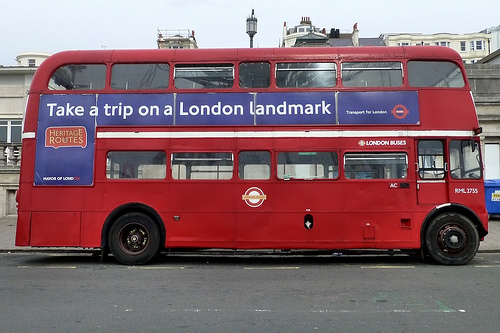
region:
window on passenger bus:
[43, 59, 105, 86]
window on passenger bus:
[168, 59, 239, 88]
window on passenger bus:
[236, 60, 276, 86]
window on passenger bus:
[275, 56, 334, 86]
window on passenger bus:
[338, 55, 402, 95]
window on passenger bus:
[405, 57, 468, 91]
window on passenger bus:
[102, 143, 170, 176]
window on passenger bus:
[168, 141, 235, 178]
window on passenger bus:
[236, 143, 278, 188]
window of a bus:
[399, 50, 466, 92]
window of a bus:
[337, 48, 407, 93]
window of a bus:
[238, 53, 279, 86]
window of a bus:
[170, 56, 235, 93]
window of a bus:
[46, 61, 111, 101]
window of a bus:
[100, 136, 170, 182]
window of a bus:
[176, 145, 231, 185]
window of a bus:
[238, 153, 273, 183]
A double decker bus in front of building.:
[12, 44, 492, 261]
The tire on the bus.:
[107, 219, 161, 271]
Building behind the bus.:
[11, 43, 73, 118]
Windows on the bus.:
[145, 53, 355, 93]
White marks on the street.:
[154, 294, 471, 313]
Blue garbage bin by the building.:
[476, 169, 499, 216]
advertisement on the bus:
[56, 90, 412, 131]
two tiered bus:
[45, 72, 480, 254]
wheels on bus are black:
[97, 212, 176, 276]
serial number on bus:
[438, 183, 485, 205]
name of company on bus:
[361, 136, 406, 146]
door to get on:
[412, 141, 452, 230]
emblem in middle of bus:
[236, 179, 268, 233]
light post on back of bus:
[243, 0, 260, 49]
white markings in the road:
[108, 297, 445, 321]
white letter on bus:
[46, 100, 56, 115]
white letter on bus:
[54, 103, 64, 118]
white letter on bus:
[64, 100, 74, 115]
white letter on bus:
[73, 104, 83, 116]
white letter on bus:
[89, 107, 100, 115]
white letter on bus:
[101, 100, 112, 117]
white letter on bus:
[109, 101, 117, 114]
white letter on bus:
[116, 100, 123, 120]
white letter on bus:
[121, 105, 132, 122]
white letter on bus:
[139, 105, 149, 115]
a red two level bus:
[9, 27, 491, 274]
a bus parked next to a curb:
[16, 37, 489, 275]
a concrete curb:
[482, 241, 498, 256]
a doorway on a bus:
[413, 132, 452, 217]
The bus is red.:
[13, 48, 489, 277]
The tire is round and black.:
[99, 206, 162, 269]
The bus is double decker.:
[34, 45, 494, 271]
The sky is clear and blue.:
[11, 5, 326, 58]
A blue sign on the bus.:
[51, 89, 398, 122]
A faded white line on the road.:
[167, 293, 484, 320]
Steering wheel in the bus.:
[420, 163, 480, 176]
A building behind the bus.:
[351, 21, 498, 68]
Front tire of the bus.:
[411, 201, 484, 271]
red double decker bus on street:
[13, 42, 492, 272]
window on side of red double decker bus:
[339, 148, 411, 184]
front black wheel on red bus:
[419, 206, 481, 269]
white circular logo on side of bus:
[239, 185, 269, 212]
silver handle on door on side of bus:
[411, 160, 423, 176]